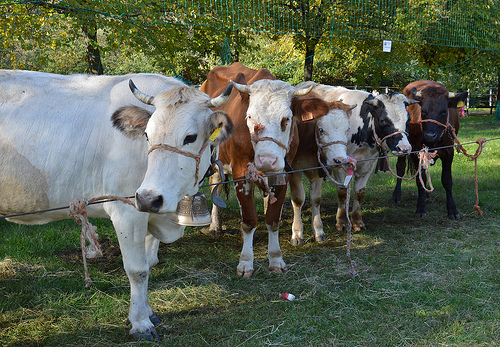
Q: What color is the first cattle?
A: White.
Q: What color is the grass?
A: Green.